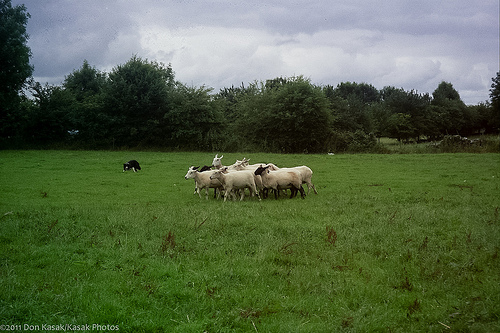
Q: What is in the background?
A: Line of trees in background.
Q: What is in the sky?
A: A sky full of clouds.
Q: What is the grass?
A: Green grass in the meadow.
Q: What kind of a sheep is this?
A: This is a white sheep.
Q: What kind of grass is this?
A: This is green grass.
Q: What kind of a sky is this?
A: This is a light blue and cloudy sky.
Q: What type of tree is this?
A: This is a green, leafy tree.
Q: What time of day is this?
A: This is early evening.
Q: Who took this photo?
A: Wendell Zuter.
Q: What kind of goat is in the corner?
A: A black goat.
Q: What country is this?
A: The United States.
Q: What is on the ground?
A: Grass.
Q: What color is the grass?
A: Green.